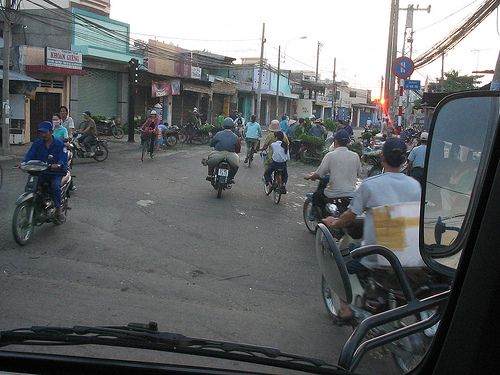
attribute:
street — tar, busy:
[8, 118, 402, 375]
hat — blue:
[38, 120, 55, 133]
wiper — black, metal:
[11, 315, 305, 366]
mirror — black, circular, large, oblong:
[427, 99, 478, 266]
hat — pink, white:
[268, 120, 281, 131]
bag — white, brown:
[372, 200, 422, 265]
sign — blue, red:
[391, 55, 411, 75]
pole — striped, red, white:
[399, 85, 406, 141]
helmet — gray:
[225, 118, 235, 128]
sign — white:
[45, 47, 83, 74]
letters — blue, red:
[51, 48, 82, 70]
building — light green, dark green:
[72, 11, 131, 133]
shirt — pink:
[145, 119, 157, 132]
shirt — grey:
[345, 174, 423, 267]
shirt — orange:
[140, 119, 162, 132]